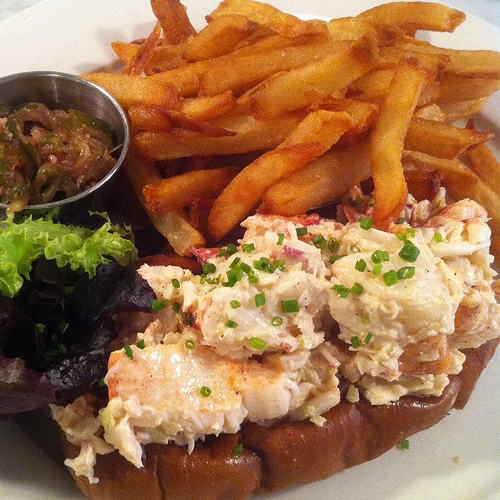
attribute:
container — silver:
[43, 74, 70, 94]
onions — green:
[47, 218, 498, 477]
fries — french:
[86, 10, 496, 249]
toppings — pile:
[216, 259, 374, 315]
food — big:
[7, 187, 494, 500]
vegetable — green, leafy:
[2, 215, 133, 305]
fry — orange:
[369, 61, 416, 205]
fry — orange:
[423, 117, 483, 147]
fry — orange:
[211, 106, 339, 210]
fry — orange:
[152, 167, 209, 204]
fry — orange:
[140, 184, 190, 216]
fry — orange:
[108, 85, 228, 103]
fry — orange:
[278, 51, 321, 59]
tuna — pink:
[117, 237, 437, 416]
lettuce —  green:
[16, 215, 78, 303]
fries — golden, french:
[119, 66, 461, 200]